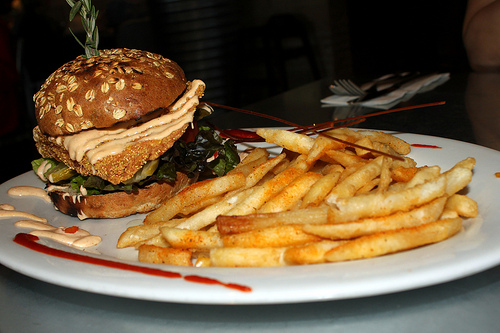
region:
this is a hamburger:
[22, 25, 474, 312]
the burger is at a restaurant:
[26, 22, 315, 267]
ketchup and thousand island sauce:
[5, 190, 176, 309]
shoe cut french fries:
[183, 174, 491, 312]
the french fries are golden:
[147, 72, 467, 267]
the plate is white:
[25, 41, 458, 318]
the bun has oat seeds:
[16, 45, 209, 180]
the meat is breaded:
[46, 112, 279, 204]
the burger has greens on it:
[11, 75, 226, 215]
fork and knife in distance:
[302, 55, 437, 150]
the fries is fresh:
[129, 122, 477, 274]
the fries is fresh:
[273, 195, 393, 303]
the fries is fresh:
[227, 184, 357, 304]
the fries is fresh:
[235, 78, 347, 245]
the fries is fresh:
[232, 110, 396, 288]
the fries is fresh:
[189, 61, 333, 198]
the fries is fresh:
[246, 160, 333, 242]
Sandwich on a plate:
[30, 35, 211, 200]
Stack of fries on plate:
[170, 104, 499, 324]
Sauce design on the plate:
[11, 177, 263, 302]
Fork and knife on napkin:
[317, 62, 462, 113]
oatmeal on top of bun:
[57, 57, 172, 119]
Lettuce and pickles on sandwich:
[38, 155, 226, 186]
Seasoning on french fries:
[266, 170, 303, 198]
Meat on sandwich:
[33, 124, 205, 164]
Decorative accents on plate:
[208, 97, 455, 173]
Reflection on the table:
[469, 75, 499, 147]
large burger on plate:
[40, 32, 221, 223]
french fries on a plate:
[194, 137, 464, 268]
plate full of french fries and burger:
[17, 25, 498, 326]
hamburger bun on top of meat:
[48, 32, 175, 136]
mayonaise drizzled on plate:
[1, 168, 102, 259]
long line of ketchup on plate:
[0, 238, 211, 289]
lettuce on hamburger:
[177, 105, 238, 172]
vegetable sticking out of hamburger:
[71, 7, 112, 58]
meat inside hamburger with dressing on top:
[48, 98, 172, 173]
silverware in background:
[290, 55, 441, 123]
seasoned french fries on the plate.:
[233, 171, 408, 250]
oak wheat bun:
[35, 65, 171, 105]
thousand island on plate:
[17, 180, 77, 240]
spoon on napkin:
[328, 81, 343, 97]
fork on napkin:
[341, 80, 362, 95]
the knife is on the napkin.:
[345, 92, 390, 107]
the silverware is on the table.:
[316, 77, 421, 112]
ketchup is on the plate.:
[66, 257, 242, 288]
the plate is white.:
[363, 262, 443, 287]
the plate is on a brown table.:
[285, 103, 322, 116]